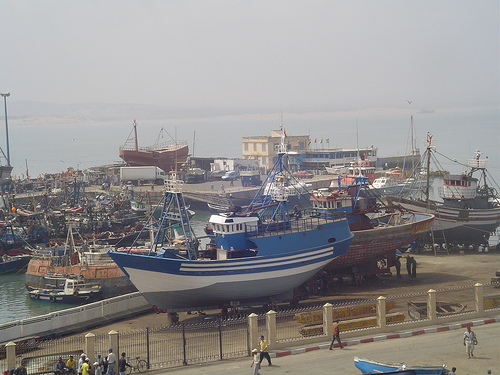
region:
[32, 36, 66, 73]
white clouds in blue sky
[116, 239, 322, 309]
blue and white boat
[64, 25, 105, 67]
white clouds in blue sky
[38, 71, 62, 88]
white clouds in blue sky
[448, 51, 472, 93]
white clouds in blue sky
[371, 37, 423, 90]
white clouds in blue sky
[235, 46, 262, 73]
white clouds in blue sky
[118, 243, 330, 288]
unfinished blue and white boat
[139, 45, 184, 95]
white clouds in blue sky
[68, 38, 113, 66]
white clouds in blue sky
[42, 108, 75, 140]
white clouds in blue sky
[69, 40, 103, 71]
white clouds in blue sky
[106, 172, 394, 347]
Blue ship is dry docked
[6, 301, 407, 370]
Columns line the fences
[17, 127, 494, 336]
Harbor is very crowded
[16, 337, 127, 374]
People gathered in a large crowd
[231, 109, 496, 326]
Large boats are near the large dock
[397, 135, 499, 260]
Boat is ready to be launched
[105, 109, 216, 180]
Ship is not ready to be in the water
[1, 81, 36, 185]
Tall mast seen in the left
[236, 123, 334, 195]
Large building on the edge of the harbor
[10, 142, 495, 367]
boats and people on elevated deck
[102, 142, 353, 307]
blue boat with metal structures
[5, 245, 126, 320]
gray and tan barge on green water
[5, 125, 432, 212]
buildings and boat on gray platform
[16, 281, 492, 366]
people standing and walking by railing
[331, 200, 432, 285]
workers standing underneath brown boat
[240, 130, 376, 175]
boxy building next to flat building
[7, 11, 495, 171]
muted sea, land and sky behind boat construction area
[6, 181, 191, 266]
small boats and boat parts on barge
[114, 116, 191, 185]
truck in front of brown ship being built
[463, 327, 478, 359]
person walking at a boat dock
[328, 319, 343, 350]
person walking at a boat dock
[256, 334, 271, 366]
person walking at a boat dock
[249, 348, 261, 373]
person walking at a boat dock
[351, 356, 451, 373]
A small blue canoe on a pier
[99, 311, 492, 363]
A metal fence along a pier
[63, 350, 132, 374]
A group of people standing on a pier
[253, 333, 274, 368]
A person in a yellow shirt walking along a pier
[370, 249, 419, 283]
A group of people standing next to a boat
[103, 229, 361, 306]
A large blue and white boat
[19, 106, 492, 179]
The ocean behind a pier full of boats